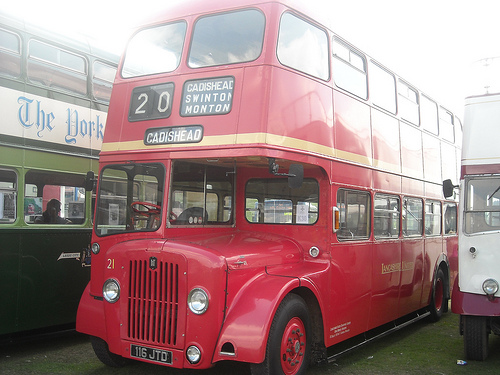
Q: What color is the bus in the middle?
A: Red.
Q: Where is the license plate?
A: On the bottom middle of bus.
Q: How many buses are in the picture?
A: Three.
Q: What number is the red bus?
A: Twenty.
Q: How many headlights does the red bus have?
A: Five.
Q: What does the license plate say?
A: 116 JTD.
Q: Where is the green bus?
A: On the left.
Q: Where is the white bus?
A: On the right.